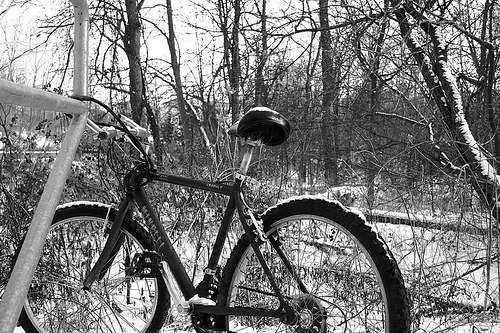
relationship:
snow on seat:
[245, 105, 283, 116] [223, 107, 293, 145]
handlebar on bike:
[86, 117, 131, 151] [9, 90, 416, 330]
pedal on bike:
[127, 247, 168, 282] [9, 90, 416, 330]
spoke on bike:
[296, 238, 348, 283] [47, 103, 440, 328]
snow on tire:
[311, 166, 442, 282] [225, 167, 463, 323]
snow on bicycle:
[281, 193, 335, 202] [9, 104, 411, 331]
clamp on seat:
[232, 172, 257, 184] [226, 107, 288, 154]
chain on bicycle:
[215, 274, 306, 329] [9, 104, 411, 331]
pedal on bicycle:
[127, 252, 162, 278] [9, 104, 411, 331]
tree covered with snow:
[386, 0, 500, 213] [0, 20, 498, 330]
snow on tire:
[261, 181, 393, 248] [210, 177, 417, 331]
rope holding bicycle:
[52, 79, 143, 159] [15, 85, 467, 330]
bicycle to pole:
[15, 85, 467, 330] [0, 74, 85, 314]